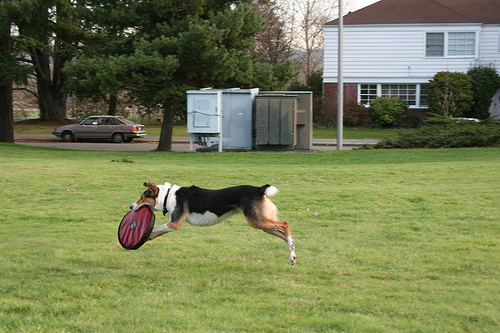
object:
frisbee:
[117, 204, 155, 249]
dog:
[130, 181, 297, 265]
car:
[52, 115, 147, 142]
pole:
[337, 0, 344, 150]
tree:
[59, 0, 292, 149]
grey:
[268, 107, 291, 136]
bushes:
[368, 95, 410, 131]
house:
[321, 0, 499, 127]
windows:
[465, 49, 473, 57]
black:
[143, 235, 151, 238]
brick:
[325, 84, 357, 115]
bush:
[426, 66, 499, 120]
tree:
[299, 2, 323, 117]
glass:
[455, 42, 462, 52]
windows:
[358, 83, 368, 90]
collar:
[160, 187, 170, 218]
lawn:
[0, 143, 500, 333]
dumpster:
[186, 87, 261, 153]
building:
[8, 36, 162, 118]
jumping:
[118, 180, 298, 267]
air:
[172, 163, 251, 167]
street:
[14, 135, 381, 152]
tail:
[257, 184, 279, 198]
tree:
[433, 72, 463, 113]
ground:
[0, 119, 500, 333]